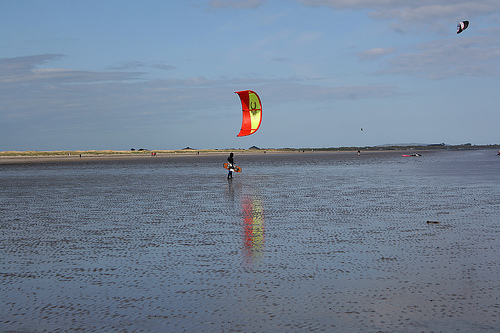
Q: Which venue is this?
A: This is a shore.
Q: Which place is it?
A: It is a shore.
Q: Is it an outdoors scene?
A: Yes, it is outdoors.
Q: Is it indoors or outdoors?
A: It is outdoors.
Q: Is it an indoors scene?
A: No, it is outdoors.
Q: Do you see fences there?
A: No, there are no fences.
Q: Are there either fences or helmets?
A: No, there are no fences or helmets.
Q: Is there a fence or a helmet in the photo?
A: No, there are no fences or helmets.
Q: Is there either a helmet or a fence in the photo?
A: No, there are no fences or helmets.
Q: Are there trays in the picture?
A: No, there are no trays.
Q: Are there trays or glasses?
A: No, there are no trays or glasses.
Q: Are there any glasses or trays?
A: No, there are no trays or glasses.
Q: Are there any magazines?
A: No, there are no magazines.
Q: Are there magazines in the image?
A: No, there are no magazines.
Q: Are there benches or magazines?
A: No, there are no magazines or benches.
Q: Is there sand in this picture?
A: Yes, there is sand.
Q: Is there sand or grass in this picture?
A: Yes, there is sand.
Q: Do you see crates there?
A: No, there are no crates.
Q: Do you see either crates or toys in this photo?
A: No, there are no crates or toys.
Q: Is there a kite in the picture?
A: Yes, there is a kite.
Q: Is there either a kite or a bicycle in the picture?
A: Yes, there is a kite.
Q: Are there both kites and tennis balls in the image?
A: No, there is a kite but no tennis balls.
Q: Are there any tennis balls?
A: No, there are no tennis balls.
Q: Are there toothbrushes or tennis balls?
A: No, there are no tennis balls or toothbrushes.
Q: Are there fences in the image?
A: No, there are no fences.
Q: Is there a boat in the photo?
A: No, there are no boats.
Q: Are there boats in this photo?
A: No, there are no boats.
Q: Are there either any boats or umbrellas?
A: No, there are no boats or umbrellas.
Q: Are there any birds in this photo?
A: No, there are no birds.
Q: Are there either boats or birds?
A: No, there are no birds or boats.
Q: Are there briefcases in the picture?
A: No, there are no briefcases.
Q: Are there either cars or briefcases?
A: No, there are no briefcases or cars.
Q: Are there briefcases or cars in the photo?
A: No, there are no briefcases or cars.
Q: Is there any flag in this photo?
A: No, there are no flags.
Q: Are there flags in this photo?
A: No, there are no flags.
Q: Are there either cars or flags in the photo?
A: No, there are no flags or cars.